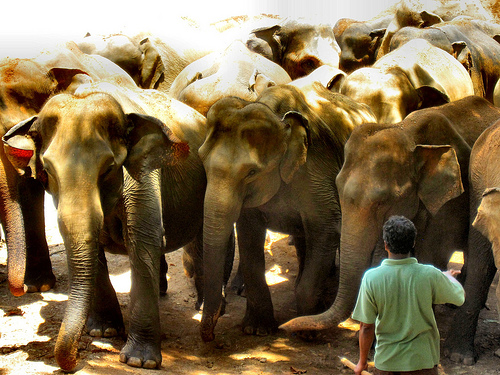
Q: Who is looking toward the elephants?
A: A man.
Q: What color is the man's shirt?
A: Green.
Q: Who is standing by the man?
A: Elephants.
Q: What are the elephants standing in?
A: The dirt.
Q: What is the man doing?
A: Standing.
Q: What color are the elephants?
A: Gray.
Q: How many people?
A: One.